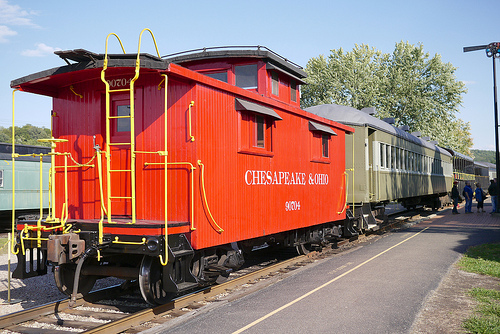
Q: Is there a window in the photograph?
A: Yes, there is a window.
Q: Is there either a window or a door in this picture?
A: Yes, there is a window.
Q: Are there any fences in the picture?
A: No, there are no fences.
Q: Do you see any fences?
A: No, there are no fences.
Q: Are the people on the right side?
A: Yes, the people are on the right of the image.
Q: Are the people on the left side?
A: No, the people are on the right of the image.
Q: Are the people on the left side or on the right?
A: The people are on the right of the image.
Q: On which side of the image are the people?
A: The people are on the right of the image.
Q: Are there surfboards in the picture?
A: No, there are no surfboards.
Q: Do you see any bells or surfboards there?
A: No, there are no surfboards or bells.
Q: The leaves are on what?
A: The leaves are on the trees.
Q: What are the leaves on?
A: The leaves are on the trees.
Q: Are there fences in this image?
A: No, there are no fences.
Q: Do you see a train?
A: Yes, there is a train.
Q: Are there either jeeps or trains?
A: Yes, there is a train.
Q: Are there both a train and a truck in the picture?
A: No, there is a train but no trucks.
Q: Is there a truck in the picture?
A: No, there are no trucks.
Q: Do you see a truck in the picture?
A: No, there are no trucks.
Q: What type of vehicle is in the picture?
A: The vehicle is a train.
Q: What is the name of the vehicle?
A: The vehicle is a train.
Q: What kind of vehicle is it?
A: The vehicle is a train.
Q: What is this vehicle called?
A: This is a train.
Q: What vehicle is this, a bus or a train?
A: This is a train.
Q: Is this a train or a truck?
A: This is a train.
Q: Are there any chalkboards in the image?
A: No, there are no chalkboards.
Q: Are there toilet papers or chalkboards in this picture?
A: No, there are no chalkboards or toilet papers.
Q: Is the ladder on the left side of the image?
A: Yes, the ladder is on the left of the image.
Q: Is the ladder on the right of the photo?
A: No, the ladder is on the left of the image.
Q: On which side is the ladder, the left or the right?
A: The ladder is on the left of the image.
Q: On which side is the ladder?
A: The ladder is on the left of the image.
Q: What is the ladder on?
A: The ladder is on the train.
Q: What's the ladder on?
A: The ladder is on the train.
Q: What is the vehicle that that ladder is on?
A: The vehicle is a train.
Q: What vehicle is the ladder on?
A: The ladder is on the train.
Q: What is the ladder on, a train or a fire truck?
A: The ladder is on a train.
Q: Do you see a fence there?
A: No, there are no fences.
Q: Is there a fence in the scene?
A: No, there are no fences.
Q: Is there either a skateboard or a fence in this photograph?
A: No, there are no fences or skateboards.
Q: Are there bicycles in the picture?
A: No, there are no bicycles.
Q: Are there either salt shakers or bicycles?
A: No, there are no bicycles or salt shakers.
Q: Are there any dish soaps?
A: No, there are no dish soaps.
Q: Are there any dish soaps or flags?
A: No, there are no dish soaps or flags.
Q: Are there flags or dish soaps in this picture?
A: No, there are no dish soaps or flags.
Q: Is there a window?
A: Yes, there is a window.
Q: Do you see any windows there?
A: Yes, there is a window.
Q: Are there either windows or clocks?
A: Yes, there is a window.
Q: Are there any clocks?
A: No, there are no clocks.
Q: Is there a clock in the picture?
A: No, there are no clocks.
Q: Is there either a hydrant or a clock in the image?
A: No, there are no clocks or fire hydrants.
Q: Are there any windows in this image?
A: Yes, there is a window.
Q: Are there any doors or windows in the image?
A: Yes, there is a window.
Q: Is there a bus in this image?
A: No, there are no buses.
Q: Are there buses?
A: No, there are no buses.